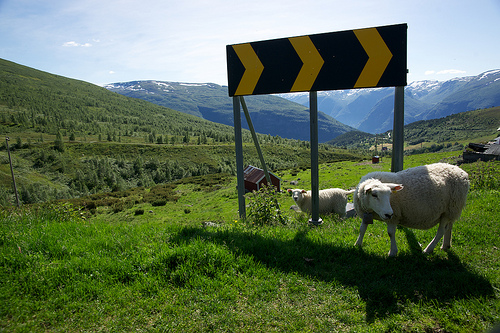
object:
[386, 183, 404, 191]
ear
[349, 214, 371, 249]
legs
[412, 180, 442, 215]
fur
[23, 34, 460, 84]
cloud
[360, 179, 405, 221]
head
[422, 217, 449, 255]
legs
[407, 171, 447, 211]
wool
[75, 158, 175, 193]
trees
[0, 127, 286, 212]
valley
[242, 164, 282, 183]
roof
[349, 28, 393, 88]
arrows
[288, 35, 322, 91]
arrows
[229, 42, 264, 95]
arrows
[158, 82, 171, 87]
snow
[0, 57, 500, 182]
distance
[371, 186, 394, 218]
face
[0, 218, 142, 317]
grass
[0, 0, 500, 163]
background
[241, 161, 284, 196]
house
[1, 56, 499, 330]
field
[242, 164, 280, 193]
building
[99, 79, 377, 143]
hill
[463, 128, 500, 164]
building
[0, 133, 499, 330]
ground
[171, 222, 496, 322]
shadow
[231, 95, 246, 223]
post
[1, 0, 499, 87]
sky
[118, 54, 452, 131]
range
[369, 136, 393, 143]
house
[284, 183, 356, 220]
sheep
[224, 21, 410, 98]
sign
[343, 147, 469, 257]
sheep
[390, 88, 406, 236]
post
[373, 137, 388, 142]
building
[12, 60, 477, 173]
mountain